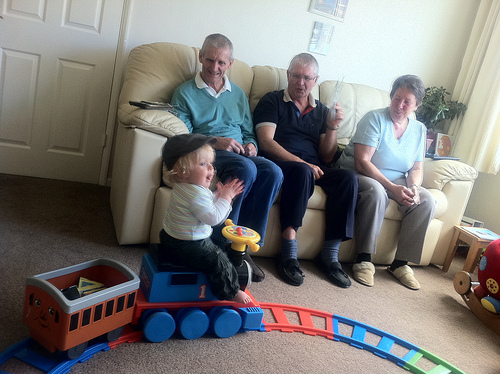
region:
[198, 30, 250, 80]
Man has gray hair.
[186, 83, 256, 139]
Man wearing blue sweater.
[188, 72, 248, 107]
Man wearing white shirt.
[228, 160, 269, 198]
Man wearing blue jeans.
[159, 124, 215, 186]
Child wearing dark cap.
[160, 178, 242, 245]
Child wearing white shirt.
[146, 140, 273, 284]
Child sitting on top of train.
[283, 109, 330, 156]
Man wearing black shirt.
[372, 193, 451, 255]
Woman wearing khaki pants.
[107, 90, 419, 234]
3 people sitting on couch.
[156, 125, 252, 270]
this is a baby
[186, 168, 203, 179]
the baby is light skinned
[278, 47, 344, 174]
this is a man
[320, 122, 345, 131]
this is a watch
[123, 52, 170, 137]
this is a couch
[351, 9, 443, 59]
this is the wall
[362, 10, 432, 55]
the wall is white in color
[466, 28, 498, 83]
this is a curtain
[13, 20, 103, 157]
this is a door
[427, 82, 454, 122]
this is a tree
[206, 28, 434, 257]
three people sitting down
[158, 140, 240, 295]
child clapping hands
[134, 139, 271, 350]
child sitting on a train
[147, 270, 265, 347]
train is blue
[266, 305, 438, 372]
tracks are red blue and green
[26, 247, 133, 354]
orange car filled with toys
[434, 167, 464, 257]
sofa is a light beige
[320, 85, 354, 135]
left hand holding an object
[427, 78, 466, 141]
green plant by the woman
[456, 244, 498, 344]
rocking toy in the corner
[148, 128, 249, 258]
The little boy is clapping his hands.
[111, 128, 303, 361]
The little boy is riding a toy train.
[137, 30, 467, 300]
Three people are sitting on the couch.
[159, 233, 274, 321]
The little boy is barefooted.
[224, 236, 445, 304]
The people on the couch are wearing shoes.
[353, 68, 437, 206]
The lady is wearing a light, blue shirt.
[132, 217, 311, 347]
The train is blue and yellow.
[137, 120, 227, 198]
The little boy is wearing a cap.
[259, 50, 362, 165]
The man is wearing a navy blue shirt.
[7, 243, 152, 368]
The toy caboose is orange.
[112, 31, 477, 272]
three people seated on a beige couch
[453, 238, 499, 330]
part of a rocking toy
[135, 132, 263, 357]
toddler sitting on a toy train engine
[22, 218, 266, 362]
open car attached to engine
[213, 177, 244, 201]
baby appears to be clapping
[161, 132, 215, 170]
child is wearing a black hat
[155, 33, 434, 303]
all three adults are looking toward the toddler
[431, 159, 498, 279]
very short and small wooden table next to couch arm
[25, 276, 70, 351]
face on back of train car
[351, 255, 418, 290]
woman is wearing slippers